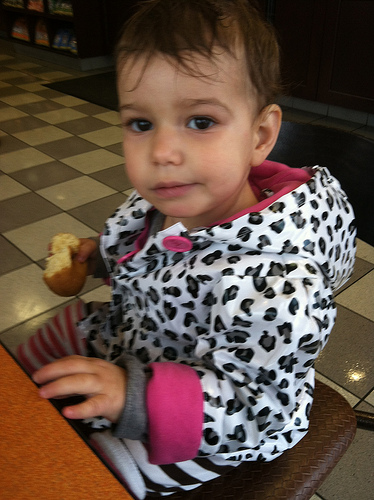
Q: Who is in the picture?
A: A little girl.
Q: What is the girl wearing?
A: A leopard jacket.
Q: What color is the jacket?
A: Black and white.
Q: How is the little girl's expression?
A: Quizzical.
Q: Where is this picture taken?
A: A restaurant.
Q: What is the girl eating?
A: A doughnut.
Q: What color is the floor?
A: Brown and white.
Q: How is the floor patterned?
A: Checkered.